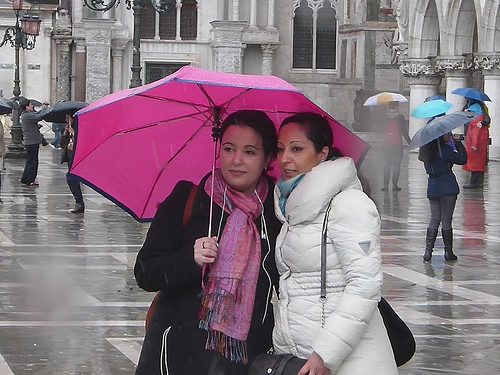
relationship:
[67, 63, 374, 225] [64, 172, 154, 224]
umbrella with trim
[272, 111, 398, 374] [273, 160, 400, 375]
woman in coat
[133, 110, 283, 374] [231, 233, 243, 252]
woman wearing pink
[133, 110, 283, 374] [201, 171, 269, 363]
woman wearing scarf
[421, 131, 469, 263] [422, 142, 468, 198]
woman wearing coat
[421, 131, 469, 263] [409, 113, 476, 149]
woman with umbrella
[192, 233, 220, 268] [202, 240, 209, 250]
hand with ring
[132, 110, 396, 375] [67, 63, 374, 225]
women sharing umbrella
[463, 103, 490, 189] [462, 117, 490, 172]
person in coat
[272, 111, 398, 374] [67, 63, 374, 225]
woman holding umbrella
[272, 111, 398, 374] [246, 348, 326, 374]
woman carrying purse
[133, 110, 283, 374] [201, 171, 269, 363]
woman in scarf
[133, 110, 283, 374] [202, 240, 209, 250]
woman wearing ring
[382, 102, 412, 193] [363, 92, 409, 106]
person holding umbrella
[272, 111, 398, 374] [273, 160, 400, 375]
woman wearing coat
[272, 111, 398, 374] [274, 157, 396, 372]
woman wearing raincoat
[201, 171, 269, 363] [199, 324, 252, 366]
scarf with tassels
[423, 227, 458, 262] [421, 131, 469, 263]
boots on woman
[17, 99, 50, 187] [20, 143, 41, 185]
man with pants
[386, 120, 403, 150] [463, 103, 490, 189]
backpack on person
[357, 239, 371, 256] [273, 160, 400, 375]
triangle on coat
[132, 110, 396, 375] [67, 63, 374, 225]
women under umbrella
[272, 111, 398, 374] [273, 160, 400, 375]
woman in puffy coat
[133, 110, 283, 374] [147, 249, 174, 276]
woman wearing black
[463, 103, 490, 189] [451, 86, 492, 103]
person holding umbrella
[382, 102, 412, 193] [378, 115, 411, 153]
person wearing coat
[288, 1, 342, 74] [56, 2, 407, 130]
window on building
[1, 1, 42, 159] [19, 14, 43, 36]
lamp with lanterns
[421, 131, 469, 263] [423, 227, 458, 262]
woman wearing boots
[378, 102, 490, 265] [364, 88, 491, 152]
people with umbrellas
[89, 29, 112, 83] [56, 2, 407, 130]
cement on building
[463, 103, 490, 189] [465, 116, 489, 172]
person wearing raincoat